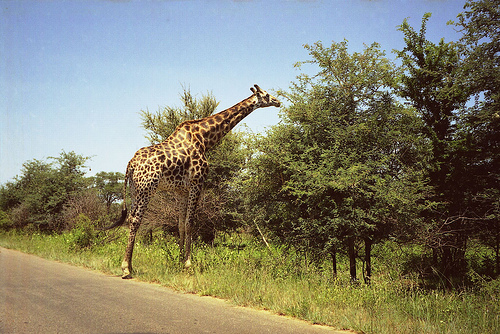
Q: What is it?
A: Giraffe.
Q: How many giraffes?
A: 1.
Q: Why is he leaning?
A: To eat.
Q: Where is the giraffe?
A: On the side of road.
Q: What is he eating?
A: Leaves.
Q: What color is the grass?
A: Green.